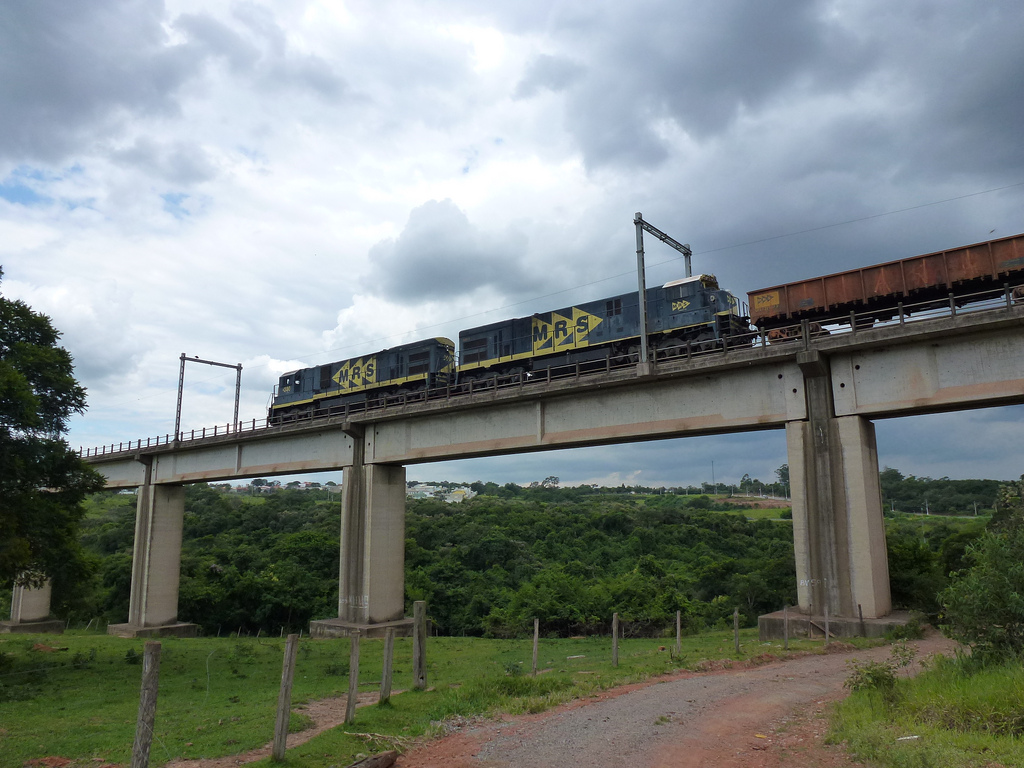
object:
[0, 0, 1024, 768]
scene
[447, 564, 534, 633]
tree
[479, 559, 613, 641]
tree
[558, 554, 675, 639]
tree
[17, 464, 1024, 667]
woods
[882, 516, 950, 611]
tree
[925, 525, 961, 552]
tree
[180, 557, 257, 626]
tree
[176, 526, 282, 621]
tree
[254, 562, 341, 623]
tree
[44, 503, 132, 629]
tree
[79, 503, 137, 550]
tree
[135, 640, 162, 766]
post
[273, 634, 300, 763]
post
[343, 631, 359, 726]
post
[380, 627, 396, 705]
post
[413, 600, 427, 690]
post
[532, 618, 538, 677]
post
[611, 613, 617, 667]
post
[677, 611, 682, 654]
post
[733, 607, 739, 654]
post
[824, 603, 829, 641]
post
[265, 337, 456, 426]
locomotive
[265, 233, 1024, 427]
train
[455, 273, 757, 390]
locomotive